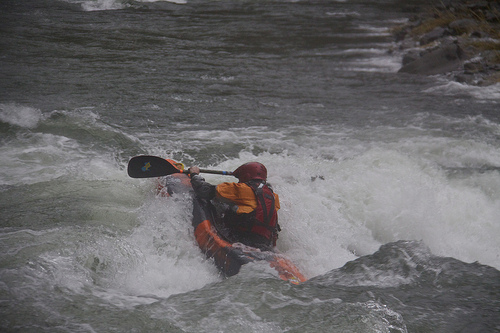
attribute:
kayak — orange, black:
[188, 188, 306, 284]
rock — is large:
[397, 32, 499, 87]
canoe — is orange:
[158, 176, 266, 257]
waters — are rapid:
[335, 141, 469, 239]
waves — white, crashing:
[326, 152, 413, 227]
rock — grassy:
[396, 42, 460, 77]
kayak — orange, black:
[188, 227, 302, 280]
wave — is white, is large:
[9, 106, 496, 321]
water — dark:
[17, 0, 499, 330]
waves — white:
[278, 60, 485, 246]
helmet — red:
[235, 163, 270, 184]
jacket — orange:
[211, 184, 293, 235]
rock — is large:
[24, 239, 499, 330]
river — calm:
[42, 213, 147, 288]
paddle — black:
[109, 150, 234, 185]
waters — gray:
[308, 88, 462, 243]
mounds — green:
[429, 5, 499, 54]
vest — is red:
[223, 183, 288, 242]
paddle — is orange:
[126, 150, 241, 181]